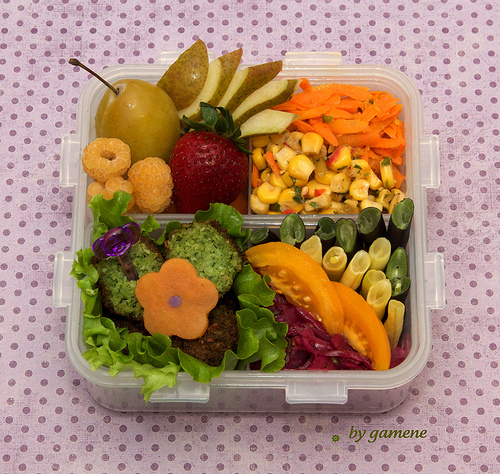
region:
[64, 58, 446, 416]
a Tupperwarea box of fruit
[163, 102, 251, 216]
a red strawberry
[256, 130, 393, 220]
yellow corn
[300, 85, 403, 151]
orange carrots sliced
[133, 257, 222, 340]
a melon made into a flower shape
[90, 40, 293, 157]
a whole pear and some pear slices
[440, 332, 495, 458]
a polkadot pattern on the table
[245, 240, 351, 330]
a sliced tomato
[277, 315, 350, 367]
beets that are sliced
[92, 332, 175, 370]
green lettuce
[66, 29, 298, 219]
assortment of fruit on tupperware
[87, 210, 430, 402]
assortment of vegetables in tupperware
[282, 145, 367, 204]
corn kernels in tupperware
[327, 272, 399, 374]
orange bell pepper slice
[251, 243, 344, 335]
orange bell pepper slice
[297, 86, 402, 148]
orange carrot shreds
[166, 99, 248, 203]
red strawberry in tupperware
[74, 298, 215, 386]
shreds of lettuce in tupperware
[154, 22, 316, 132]
slices of pear in tupperware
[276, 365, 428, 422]
clear plastic tupperware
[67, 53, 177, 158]
A green pear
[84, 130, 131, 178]
A piece of orange fruit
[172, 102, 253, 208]
A red strawberry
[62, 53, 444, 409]
A container of fruit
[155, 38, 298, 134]
Sliced pieces of pears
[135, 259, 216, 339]
Flower shaped piece of fruit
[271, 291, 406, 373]
Magenta colored food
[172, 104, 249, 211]
A red strawberry in a container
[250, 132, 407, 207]
Yellow corn in a container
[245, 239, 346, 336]
A slice of a orange fruit or vegetable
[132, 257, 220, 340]
a star shaped carrot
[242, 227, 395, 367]
two half slices of tomatoes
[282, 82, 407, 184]
small slices of carrot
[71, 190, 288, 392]
a lettuce wrapping on the bottom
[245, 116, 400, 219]
marinated corn with onions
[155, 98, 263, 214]
a red strawberry with the top leaf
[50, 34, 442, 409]
a salad lunch box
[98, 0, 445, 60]
polka dot table clothe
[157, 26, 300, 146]
individual slices of pear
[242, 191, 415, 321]
chopped onions in long pieces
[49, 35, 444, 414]
A container of food.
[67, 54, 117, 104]
A steam on a fruit.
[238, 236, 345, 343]
A piece of tomato.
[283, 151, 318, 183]
A yellow corn kernel.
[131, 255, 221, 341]
A piece of food shaped like a flower.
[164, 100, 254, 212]
A red strawberry in a plastic container.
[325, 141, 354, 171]
A red and yellow kernel.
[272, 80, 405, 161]
Orange shredded pieces of food.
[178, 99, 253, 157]
The leaves of a strawberry.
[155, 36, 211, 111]
A slice of fruit.